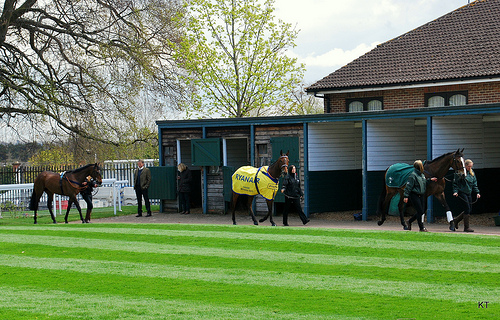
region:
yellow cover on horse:
[231, 154, 289, 194]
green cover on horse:
[388, 170, 443, 202]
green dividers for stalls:
[175, 118, 466, 228]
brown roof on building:
[348, 0, 495, 81]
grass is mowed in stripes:
[38, 233, 325, 317]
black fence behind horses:
[7, 165, 161, 202]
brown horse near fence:
[28, 164, 118, 229]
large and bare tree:
[8, 10, 218, 108]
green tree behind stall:
[155, 4, 296, 108]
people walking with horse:
[388, 155, 488, 239]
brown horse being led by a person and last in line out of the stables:
[26, 157, 103, 222]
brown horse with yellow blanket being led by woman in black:
[230, 150, 315, 220]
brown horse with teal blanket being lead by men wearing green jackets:
[370, 146, 471, 231]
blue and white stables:
[135, 95, 495, 220]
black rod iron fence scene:
[5, 155, 155, 205]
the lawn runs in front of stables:
[5, 200, 495, 310]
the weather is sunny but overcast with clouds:
[1, 0, 463, 110]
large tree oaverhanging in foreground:
[0, 0, 220, 205]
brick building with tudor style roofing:
[300, 2, 497, 108]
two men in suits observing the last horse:
[128, 148, 195, 223]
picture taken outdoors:
[4, 10, 496, 297]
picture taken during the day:
[7, 8, 478, 315]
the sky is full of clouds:
[310, 17, 341, 45]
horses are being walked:
[2, 133, 476, 257]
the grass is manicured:
[67, 223, 278, 288]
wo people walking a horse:
[384, 140, 486, 208]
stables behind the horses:
[154, 123, 488, 224]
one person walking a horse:
[278, 153, 303, 218]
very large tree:
[12, 14, 232, 126]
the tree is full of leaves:
[8, 10, 273, 101]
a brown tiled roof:
[325, 43, 471, 90]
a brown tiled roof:
[352, 18, 491, 93]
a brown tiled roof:
[304, 25, 441, 77]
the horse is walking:
[23, 149, 133, 234]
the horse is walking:
[226, 135, 344, 246]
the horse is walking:
[354, 121, 498, 261]